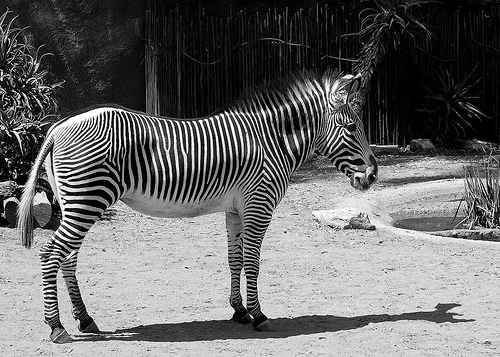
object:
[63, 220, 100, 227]
black stripe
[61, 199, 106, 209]
black stripe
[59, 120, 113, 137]
black stripe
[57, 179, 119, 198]
black stripe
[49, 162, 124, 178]
black stripe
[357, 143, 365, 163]
stripe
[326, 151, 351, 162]
stripe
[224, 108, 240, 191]
stripe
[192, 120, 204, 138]
stripe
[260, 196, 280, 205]
stripe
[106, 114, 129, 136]
stripe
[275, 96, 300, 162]
stripe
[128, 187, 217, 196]
stripe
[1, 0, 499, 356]
habitat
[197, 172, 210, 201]
stripe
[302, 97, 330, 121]
stripe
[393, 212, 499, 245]
water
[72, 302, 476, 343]
shadow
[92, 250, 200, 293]
dirt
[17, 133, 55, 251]
tail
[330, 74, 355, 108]
ear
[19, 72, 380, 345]
zebra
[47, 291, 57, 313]
stripe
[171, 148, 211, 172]
black stripe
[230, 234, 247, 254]
stripe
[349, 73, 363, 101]
left ear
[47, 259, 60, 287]
stripe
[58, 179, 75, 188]
stripe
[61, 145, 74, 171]
stripe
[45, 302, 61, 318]
stripe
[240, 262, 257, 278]
stripe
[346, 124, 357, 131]
eye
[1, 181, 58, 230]
wood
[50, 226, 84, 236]
stripe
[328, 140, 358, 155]
stripe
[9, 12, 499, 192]
wall